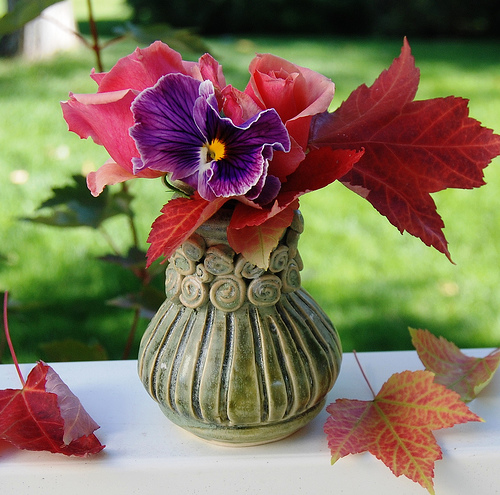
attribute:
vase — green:
[131, 202, 352, 448]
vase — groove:
[107, 199, 354, 444]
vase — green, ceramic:
[121, 205, 343, 456]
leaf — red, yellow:
[324, 350, 484, 492]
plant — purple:
[1, 0, 223, 360]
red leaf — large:
[296, 37, 498, 267]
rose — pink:
[223, 52, 335, 176]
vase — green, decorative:
[137, 211, 342, 446]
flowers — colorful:
[59, 35, 496, 271]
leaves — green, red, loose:
[330, 339, 455, 473]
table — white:
[4, 358, 490, 493]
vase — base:
[143, 357, 340, 450]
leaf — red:
[0, 290, 107, 455]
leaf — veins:
[328, 339, 485, 494]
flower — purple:
[160, 91, 252, 178]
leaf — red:
[312, 44, 498, 256]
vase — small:
[159, 281, 326, 406]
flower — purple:
[123, 72, 294, 204]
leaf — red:
[1, 336, 95, 468]